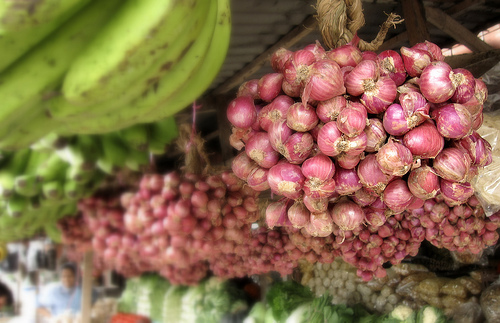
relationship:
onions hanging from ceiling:
[223, 28, 493, 238] [126, 2, 349, 169]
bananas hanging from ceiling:
[170, 6, 212, 129] [232, 0, 314, 45]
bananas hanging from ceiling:
[71, 2, 161, 84] [232, 0, 314, 45]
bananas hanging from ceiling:
[17, 8, 103, 111] [232, 0, 314, 45]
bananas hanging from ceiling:
[2, 6, 49, 56] [232, 0, 314, 45]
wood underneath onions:
[297, 248, 498, 316] [75, 34, 492, 290]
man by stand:
[39, 264, 84, 316] [5, 1, 462, 305]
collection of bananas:
[6, 7, 232, 117] [14, 33, 212, 155]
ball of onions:
[227, 50, 484, 207] [216, 89, 410, 199]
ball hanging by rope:
[227, 50, 484, 207] [149, 117, 297, 172]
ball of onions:
[221, 50, 484, 207] [256, 50, 474, 261]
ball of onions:
[227, 50, 484, 207] [214, 22, 495, 253]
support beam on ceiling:
[432, 10, 489, 53] [232, 0, 314, 45]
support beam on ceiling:
[399, 0, 430, 42] [232, 0, 314, 45]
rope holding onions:
[312, 0, 399, 52] [61, 47, 498, 284]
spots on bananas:
[84, 36, 183, 101] [0, 5, 233, 128]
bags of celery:
[131, 279, 320, 318] [112, 272, 445, 321]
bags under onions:
[131, 279, 320, 318] [268, 67, 396, 158]